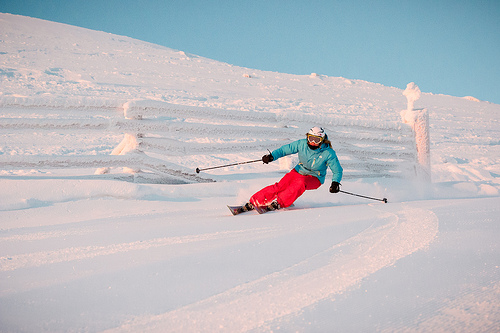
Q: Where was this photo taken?
A: Outside.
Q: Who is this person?
A: A skier.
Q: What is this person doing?
A: Skiing.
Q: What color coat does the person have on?
A: Blue.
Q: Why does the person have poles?
A: So that they can ski.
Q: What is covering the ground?
A: Snow.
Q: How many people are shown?
A: 1.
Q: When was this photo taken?
A: During the day.